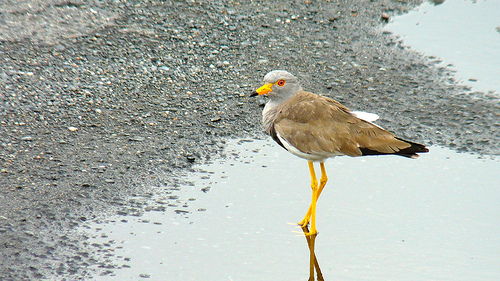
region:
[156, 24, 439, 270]
a small wading bird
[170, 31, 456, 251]
this is a bird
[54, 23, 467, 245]
the bird is on the beach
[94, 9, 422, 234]
the beach is pebbly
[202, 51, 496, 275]
the bird is reflected in the water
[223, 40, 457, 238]
the tail feathers are black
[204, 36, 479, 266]
the eyes are red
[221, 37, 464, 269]
the legs are yellow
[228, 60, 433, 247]
the wings are brown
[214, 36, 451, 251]
the bird has long legs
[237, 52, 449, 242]
the bird is perched on the ground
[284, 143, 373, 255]
the legs are long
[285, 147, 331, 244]
legs are yellow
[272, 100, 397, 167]
the wings are brown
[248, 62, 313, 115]
the bird's head is gray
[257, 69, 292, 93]
the eye is orange and black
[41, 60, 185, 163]
the ground has stones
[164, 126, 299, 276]
the ground has watter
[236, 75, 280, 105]
the beak is yellow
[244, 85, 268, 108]
the tip is black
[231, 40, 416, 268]
a beautiful bird in the water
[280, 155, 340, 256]
the bird has yellow legs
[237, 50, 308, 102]
the bird has a yellow & black beak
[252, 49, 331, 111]
the bird has an orange eye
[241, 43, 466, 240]
the bird is white, brown & black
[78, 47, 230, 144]
the shore is littered with broken shells or gravel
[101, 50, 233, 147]
the shore is grey in color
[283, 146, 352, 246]
the bird has very long legs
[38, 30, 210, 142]
there are multicolored stones/shells on the beach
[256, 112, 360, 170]
the bird's belly is white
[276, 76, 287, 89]
Eye is red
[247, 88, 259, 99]
Front of beak is black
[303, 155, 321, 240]
Leg is yellow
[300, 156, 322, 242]
Leg and foot in water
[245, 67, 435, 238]
Small bird standing in water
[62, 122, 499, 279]
Puddle next to puddle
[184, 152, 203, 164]
Black rock near puddle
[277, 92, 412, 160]
Feathers are tan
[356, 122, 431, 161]
Dark brown feather under tan feathers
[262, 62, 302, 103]
Head is gray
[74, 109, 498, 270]
a puddle of water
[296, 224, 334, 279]
the reflection of bird legs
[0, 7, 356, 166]
a gravel road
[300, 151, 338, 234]
long yellow bird legs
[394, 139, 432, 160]
black tail feathers on a bird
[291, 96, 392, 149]
pale brown wing feathers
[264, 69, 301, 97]
a white head on a bird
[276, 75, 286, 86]
a yellow eye on a bird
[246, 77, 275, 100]
a yellow beak with a black tip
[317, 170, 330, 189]
a bent joint of a bird leg